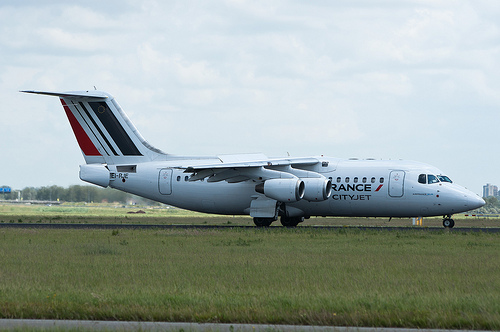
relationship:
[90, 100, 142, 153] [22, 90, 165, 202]
stripe on tail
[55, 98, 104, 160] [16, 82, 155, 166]
red stripe on tail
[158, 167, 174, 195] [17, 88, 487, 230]
backdoor near back of plane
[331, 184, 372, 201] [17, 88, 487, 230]
brand on plane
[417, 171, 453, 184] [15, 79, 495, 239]
windshield of plane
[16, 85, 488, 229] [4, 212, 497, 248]
airplane on tarmac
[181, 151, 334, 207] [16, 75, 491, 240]
wing of airplane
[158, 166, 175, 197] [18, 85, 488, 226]
backdoor on airplane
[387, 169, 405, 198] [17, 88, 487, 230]
door on plane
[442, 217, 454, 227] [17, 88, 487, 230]
tire on front of plane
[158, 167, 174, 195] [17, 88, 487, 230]
backdoor on rear of plane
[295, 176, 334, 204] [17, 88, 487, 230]
engine on plane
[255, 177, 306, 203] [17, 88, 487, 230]
engine on plane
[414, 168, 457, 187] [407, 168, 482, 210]
windows in cockpit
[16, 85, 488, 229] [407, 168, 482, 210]
airplane has cockpit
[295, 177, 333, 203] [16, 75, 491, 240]
engine on side of airplane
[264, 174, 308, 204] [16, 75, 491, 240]
engine on side of airplane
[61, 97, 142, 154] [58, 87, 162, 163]
stripe on side of fin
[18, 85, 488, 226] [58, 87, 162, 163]
airplane has fin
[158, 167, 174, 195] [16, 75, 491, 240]
backdoor on back of airplane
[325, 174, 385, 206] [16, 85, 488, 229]
logo on side of airplane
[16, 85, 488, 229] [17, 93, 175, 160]
airplane has tail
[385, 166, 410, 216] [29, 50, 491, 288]
door of airplane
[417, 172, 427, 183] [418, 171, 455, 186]
window of cockpit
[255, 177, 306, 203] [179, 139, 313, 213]
engine under wing